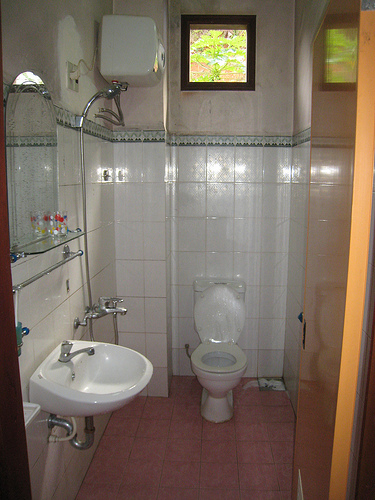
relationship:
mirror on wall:
[6, 72, 83, 256] [3, 2, 131, 399]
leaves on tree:
[198, 38, 213, 48] [197, 37, 237, 80]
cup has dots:
[50, 211, 68, 238] [54, 218, 66, 234]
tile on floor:
[242, 446, 285, 468] [113, 373, 290, 499]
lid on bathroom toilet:
[194, 287, 239, 342] [192, 279, 247, 420]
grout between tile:
[231, 441, 244, 468] [242, 446, 285, 468]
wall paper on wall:
[57, 106, 165, 142] [3, 2, 131, 399]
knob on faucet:
[59, 338, 72, 354] [61, 340, 94, 361]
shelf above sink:
[19, 224, 84, 256] [31, 340, 153, 420]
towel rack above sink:
[10, 245, 88, 291] [31, 340, 153, 420]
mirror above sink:
[6, 72, 83, 256] [31, 340, 153, 420]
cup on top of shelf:
[50, 211, 68, 238] [19, 224, 84, 256]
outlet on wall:
[67, 64, 81, 93] [3, 2, 131, 399]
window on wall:
[179, 15, 257, 88] [3, 2, 131, 399]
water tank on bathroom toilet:
[194, 279, 247, 333] [192, 279, 247, 420]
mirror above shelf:
[6, 72, 83, 256] [19, 224, 84, 256]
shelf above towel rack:
[19, 224, 84, 256] [10, 245, 88, 291]